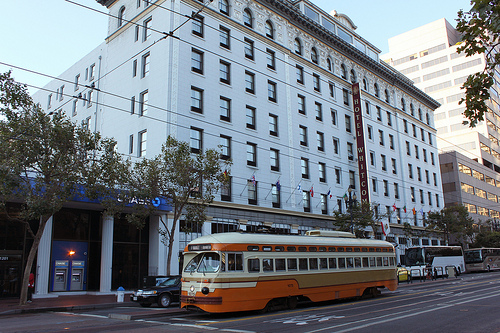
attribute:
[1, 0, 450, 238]
building — white, hotel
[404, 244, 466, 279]
bus — white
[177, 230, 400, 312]
bus — orange, vintage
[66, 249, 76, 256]
light — yellow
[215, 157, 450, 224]
flags — row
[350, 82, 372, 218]
sign — vertical, white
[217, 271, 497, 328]
lines — white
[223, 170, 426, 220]
flags — multiple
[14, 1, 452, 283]
building — large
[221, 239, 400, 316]
bus side — orange, white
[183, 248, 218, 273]
window — windshield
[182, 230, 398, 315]
trolley car — orange, brown, white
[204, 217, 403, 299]
car — large, orange, brown, white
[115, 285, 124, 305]
fire hydrant — white, blue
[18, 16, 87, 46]
sky — blue, daytime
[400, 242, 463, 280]
rails — bicycle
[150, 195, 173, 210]
sign — Chase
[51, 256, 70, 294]
cash machine — pictured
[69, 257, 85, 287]
cash machine — pictured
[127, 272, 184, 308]
car — black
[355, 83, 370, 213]
lettering — white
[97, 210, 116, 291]
column — white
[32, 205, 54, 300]
column — white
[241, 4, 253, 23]
window — arched